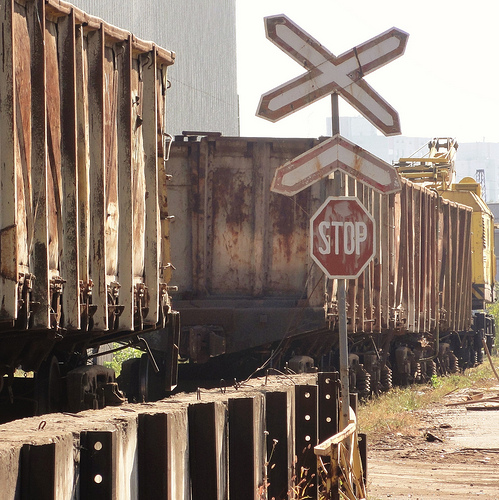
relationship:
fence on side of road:
[313, 403, 366, 499] [367, 356, 498, 497]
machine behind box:
[396, 138, 498, 319] [173, 130, 478, 387]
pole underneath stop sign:
[329, 89, 355, 432] [308, 196, 378, 283]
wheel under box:
[33, 352, 119, 414] [3, 0, 181, 332]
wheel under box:
[290, 354, 318, 377] [173, 130, 478, 387]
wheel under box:
[364, 350, 388, 395] [173, 130, 478, 387]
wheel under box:
[393, 344, 418, 386] [173, 130, 478, 387]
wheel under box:
[438, 341, 461, 377] [173, 130, 478, 387]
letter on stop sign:
[316, 219, 332, 258] [308, 196, 378, 283]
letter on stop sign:
[331, 217, 346, 256] [308, 196, 378, 283]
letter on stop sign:
[342, 217, 359, 259] [308, 196, 378, 283]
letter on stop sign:
[354, 216, 370, 256] [308, 196, 378, 283]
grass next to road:
[346, 300, 497, 441] [367, 356, 498, 497]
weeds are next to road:
[482, 300, 498, 355] [367, 356, 498, 497]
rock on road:
[438, 420, 452, 432] [367, 356, 498, 497]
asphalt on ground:
[418, 389, 498, 455] [360, 309, 498, 499]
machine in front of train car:
[396, 138, 498, 319] [170, 128, 475, 399]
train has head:
[161, 128, 497, 405] [432, 184, 496, 318]